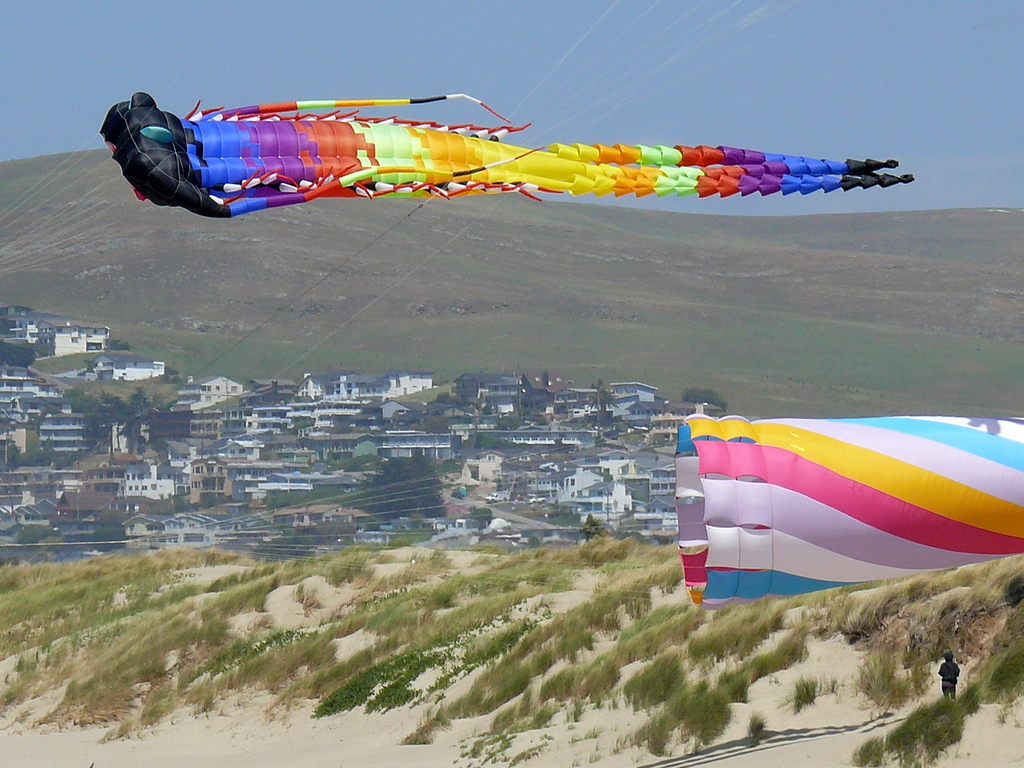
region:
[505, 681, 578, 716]
long green and yellow grass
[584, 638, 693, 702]
long green and yellow grass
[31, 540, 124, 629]
long green and yellow grass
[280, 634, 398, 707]
long green and yellow grass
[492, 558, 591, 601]
long green and yellow grass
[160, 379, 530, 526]
houses in distance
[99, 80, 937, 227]
wind sock is rainbow colored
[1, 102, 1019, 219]
sky is blue and clear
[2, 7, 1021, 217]
windsock flyingi n the sky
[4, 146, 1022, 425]
rolling green and brown hills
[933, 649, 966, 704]
man is wearng a black shirt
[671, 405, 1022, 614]
windsock is pastel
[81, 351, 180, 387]
house is white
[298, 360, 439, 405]
large house is white with dark gray roof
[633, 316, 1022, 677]
multi colored balloon in air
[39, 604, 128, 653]
tall green and yellow grass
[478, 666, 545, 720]
tall green and yellow grass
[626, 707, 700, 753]
tall green and yellow grass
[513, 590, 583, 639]
tall green and yellow grass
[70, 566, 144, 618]
tall green and yellow grass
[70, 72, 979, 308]
multi colored balloon in sky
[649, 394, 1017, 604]
multi colored balloon in sky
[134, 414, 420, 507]
houses in distance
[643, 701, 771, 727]
tall green and yellow grass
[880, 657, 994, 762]
tall green and yellow grass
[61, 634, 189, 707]
tall green and yellow grass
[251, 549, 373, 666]
tall green and yellow grass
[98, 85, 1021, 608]
Two wind socks floating in the air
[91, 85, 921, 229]
Wind sock shaped like an animal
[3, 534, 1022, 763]
Sand dunes with grass growing on them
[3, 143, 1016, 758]
City between two large hill ranges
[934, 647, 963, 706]
Person wearing black jacket and pants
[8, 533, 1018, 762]
Person standing on grassy sand dunes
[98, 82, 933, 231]
Wind sock with black head and tail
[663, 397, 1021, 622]
Circular wind sock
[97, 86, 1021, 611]
Animal wind sock floating higher than circular wind sock